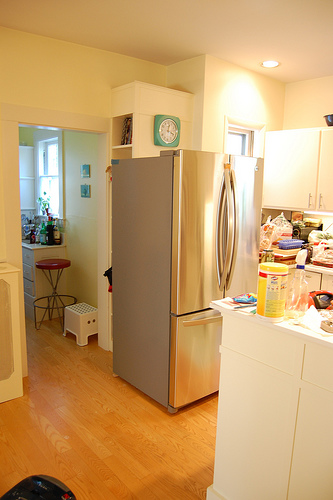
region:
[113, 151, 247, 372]
a stainless steel fridge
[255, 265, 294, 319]
a tub of clorox wipes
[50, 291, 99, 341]
a small white step stool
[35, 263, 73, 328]
a small red bar stool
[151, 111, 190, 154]
a small blue wall clock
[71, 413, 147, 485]
brown hard wood flooring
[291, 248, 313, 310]
a clear empty spray bottle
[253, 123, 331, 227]
a large white cabinet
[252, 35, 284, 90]
a small light on the ceiling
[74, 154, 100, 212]
art nailed to the wall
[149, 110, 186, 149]
green framed clock on wall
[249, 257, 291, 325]
yellow plastic container on top of countertop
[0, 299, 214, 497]
hardwood floors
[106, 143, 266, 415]
stainless steel refrigerator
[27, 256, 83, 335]
red stool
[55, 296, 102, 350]
short white footstool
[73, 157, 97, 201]
two pictures hanging on wall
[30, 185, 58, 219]
plant in windowsill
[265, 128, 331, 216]
white cabinets in kitchen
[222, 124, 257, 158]
window in kitchen on side of refrigerator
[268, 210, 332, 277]
a counter congested with different items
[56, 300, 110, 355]
a foot stood sitting near wall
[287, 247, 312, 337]
a spray bottle sitting on top of a counter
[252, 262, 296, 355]
wipes sitting on top of a counter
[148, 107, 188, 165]
a clock hanging above refridgerator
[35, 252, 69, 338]
a stool standing near a counter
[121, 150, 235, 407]
a refridgerator standing under a clock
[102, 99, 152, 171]
a shelf standing behind a refridgerator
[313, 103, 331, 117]
a bowl sitting on top of cabinets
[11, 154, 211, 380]
a refridgerator standing near a doorway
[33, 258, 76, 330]
a red stool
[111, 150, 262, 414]
a silver refrigerator in a kitchen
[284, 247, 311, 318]
a spray bottle on a counter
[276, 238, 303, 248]
a blue plastic container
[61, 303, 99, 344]
a white stepladder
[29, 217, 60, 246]
bottle on a counter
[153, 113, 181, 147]
a green clock on the wall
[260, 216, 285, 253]
a plastic bag on a counter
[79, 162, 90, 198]
two small paintings on the wall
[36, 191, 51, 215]
a green plant on the windowsill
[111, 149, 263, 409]
large refrigerator with two silver doors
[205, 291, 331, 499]
section of a white counter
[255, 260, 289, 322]
container of disinfecting wipes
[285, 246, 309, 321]
spray bottle that appears empty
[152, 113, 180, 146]
wall clock with a green border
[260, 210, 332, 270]
items in wrappings and containers piled on counter-top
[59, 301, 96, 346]
white plastic step stool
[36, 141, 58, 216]
plant leaves in front of a window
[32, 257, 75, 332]
stool with a red seat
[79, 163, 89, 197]
two bluish tile-sized images